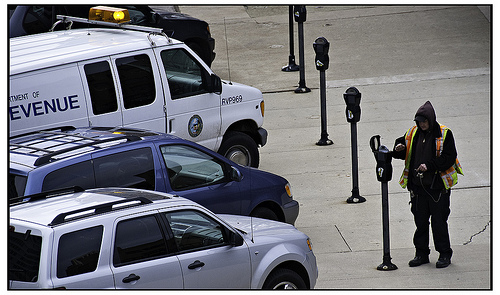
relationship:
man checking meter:
[391, 99, 464, 268] [369, 134, 397, 271]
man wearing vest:
[391, 99, 464, 268] [398, 124, 465, 189]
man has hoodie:
[391, 99, 464, 268] [391, 100, 457, 195]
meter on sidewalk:
[369, 134, 397, 271] [150, 5, 492, 290]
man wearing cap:
[391, 99, 464, 268] [413, 113, 427, 124]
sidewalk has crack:
[150, 5, 492, 290] [462, 218, 492, 246]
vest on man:
[398, 124, 465, 189] [391, 99, 464, 268]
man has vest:
[391, 99, 464, 268] [398, 124, 465, 189]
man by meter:
[391, 99, 464, 268] [369, 134, 397, 271]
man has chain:
[391, 99, 464, 268] [420, 176, 445, 202]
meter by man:
[369, 134, 397, 271] [391, 99, 464, 268]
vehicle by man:
[9, 186, 319, 292] [391, 99, 464, 268]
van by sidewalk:
[8, 126, 299, 227] [150, 5, 492, 290]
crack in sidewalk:
[462, 218, 492, 246] [150, 5, 492, 290]